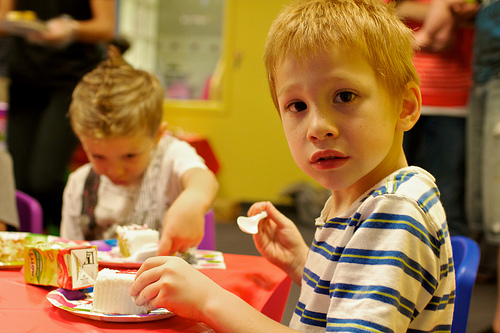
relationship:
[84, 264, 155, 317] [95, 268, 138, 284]
cake has frosting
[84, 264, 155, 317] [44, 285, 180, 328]
cake on plate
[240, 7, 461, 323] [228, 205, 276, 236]
boy has spoon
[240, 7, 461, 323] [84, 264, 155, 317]
boy has cake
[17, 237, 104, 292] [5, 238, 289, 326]
juice on table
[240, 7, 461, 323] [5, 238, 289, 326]
boy at table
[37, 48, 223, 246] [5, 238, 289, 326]
boy at table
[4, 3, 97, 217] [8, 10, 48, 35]
lady has plate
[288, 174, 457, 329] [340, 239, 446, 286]
shirt has stripes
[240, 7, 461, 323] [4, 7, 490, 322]
boy in image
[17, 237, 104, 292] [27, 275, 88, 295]
juice on side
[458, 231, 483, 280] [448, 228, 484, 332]
back of chair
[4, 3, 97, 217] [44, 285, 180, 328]
lady has plate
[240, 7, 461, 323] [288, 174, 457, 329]
boy has shirt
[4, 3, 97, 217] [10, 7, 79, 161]
lady has clothes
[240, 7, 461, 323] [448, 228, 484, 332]
boy in chair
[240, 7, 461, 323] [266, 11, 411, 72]
boy has hair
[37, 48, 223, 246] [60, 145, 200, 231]
boy has shirt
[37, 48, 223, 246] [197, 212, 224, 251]
boy in chair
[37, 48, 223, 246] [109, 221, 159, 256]
boy has cake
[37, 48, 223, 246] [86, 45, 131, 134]
boy has mohawk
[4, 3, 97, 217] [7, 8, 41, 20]
lady has cake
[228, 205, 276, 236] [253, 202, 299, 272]
spoon in hand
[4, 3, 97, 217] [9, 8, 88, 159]
lady in black